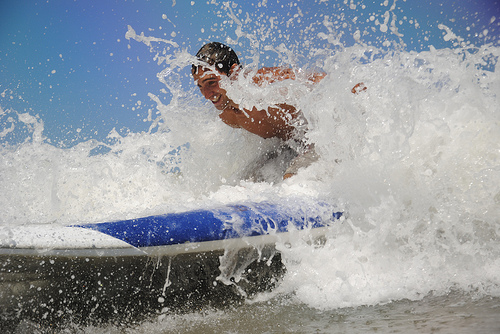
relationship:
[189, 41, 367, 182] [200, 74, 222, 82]
man has eyebrow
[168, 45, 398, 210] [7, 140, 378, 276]
man riding on surfboard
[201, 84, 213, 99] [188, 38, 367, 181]
nose of a man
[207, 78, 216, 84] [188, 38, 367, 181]
eye of a man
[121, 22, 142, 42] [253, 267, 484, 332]
drop of water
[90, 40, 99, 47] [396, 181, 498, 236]
drop of water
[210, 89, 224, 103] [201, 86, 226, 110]
teeth in man's mouth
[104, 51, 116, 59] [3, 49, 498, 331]
drop in water